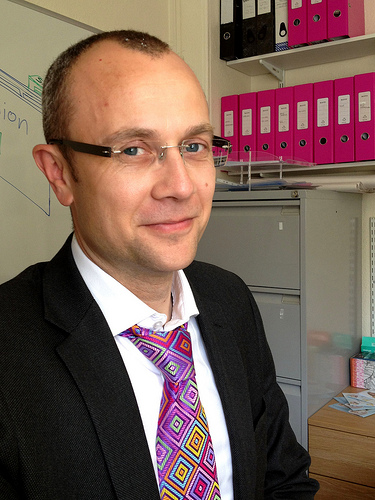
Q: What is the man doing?
A: Grinning.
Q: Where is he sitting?
A: In an office.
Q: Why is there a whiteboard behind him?
A: For communication.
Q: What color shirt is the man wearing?
A: White.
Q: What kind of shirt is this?
A: A button down.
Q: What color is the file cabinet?
A: Gray.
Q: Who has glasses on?
A: The man.